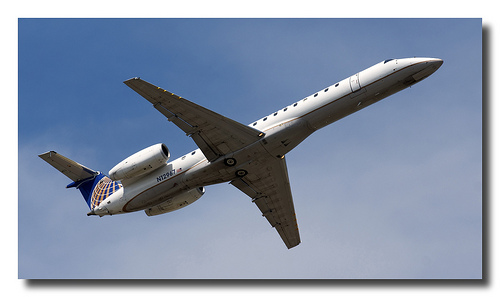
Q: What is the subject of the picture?
A: An airplane.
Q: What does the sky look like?
A: Completely clear.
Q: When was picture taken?
A: During the day.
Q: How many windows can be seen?
A: 11.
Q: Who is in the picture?
A: No one can be seen.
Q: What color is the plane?
A: White.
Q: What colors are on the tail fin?
A: Blue and red.